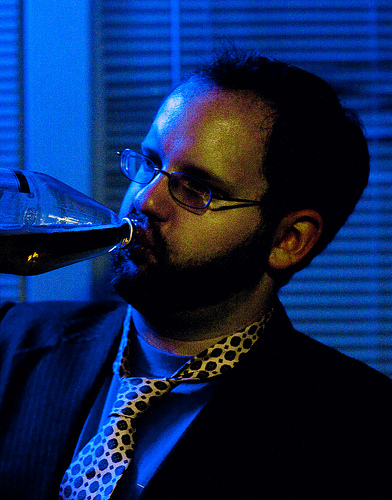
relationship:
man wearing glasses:
[0, 42, 372, 499] [105, 146, 268, 219]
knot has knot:
[60, 300, 277, 496] [75, 370, 209, 426]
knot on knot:
[75, 370, 209, 426] [60, 300, 277, 496]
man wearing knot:
[0, 42, 372, 499] [60, 300, 277, 496]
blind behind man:
[98, 9, 387, 383] [0, 42, 372, 499]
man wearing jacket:
[0, 42, 372, 499] [1, 279, 389, 499]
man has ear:
[0, 42, 372, 499] [266, 199, 324, 276]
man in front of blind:
[0, 42, 372, 499] [98, 9, 387, 383]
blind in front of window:
[98, 9, 387, 383] [101, 2, 387, 363]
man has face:
[0, 42, 372, 499] [106, 78, 262, 292]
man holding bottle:
[0, 42, 372, 499] [2, 167, 143, 279]